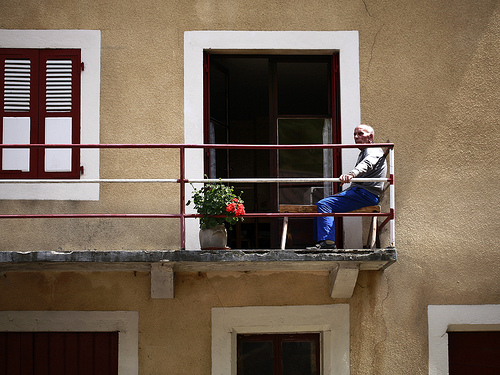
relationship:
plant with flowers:
[185, 172, 248, 230] [224, 198, 246, 217]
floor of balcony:
[2, 249, 397, 267] [5, 139, 390, 296]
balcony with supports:
[5, 139, 390, 296] [143, 270, 379, 306]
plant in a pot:
[175, 177, 247, 226] [195, 224, 230, 249]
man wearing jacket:
[306, 124, 388, 250] [344, 146, 386, 193]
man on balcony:
[306, 124, 388, 250] [1, 138, 398, 270]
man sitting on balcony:
[306, 124, 388, 250] [5, 139, 390, 296]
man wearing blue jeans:
[306, 124, 388, 250] [314, 183, 382, 242]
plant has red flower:
[185, 172, 248, 230] [222, 194, 249, 219]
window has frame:
[1, 15, 105, 198] [1, 27, 104, 202]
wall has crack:
[0, 1, 499, 374] [363, 0, 385, 77]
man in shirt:
[306, 124, 388, 250] [346, 146, 386, 189]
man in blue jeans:
[306, 124, 388, 250] [314, 183, 382, 242]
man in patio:
[306, 124, 388, 250] [11, 130, 403, 303]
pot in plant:
[197, 223, 230, 250] [175, 177, 247, 226]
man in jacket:
[306, 124, 388, 250] [349, 146, 388, 198]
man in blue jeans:
[313, 124, 387, 246] [314, 183, 376, 243]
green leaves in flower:
[185, 181, 243, 236] [225, 197, 245, 218]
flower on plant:
[226, 197, 246, 217] [151, 156, 251, 250]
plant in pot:
[185, 172, 248, 230] [186, 217, 237, 260]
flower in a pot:
[224, 192, 258, 232] [184, 172, 250, 250]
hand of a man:
[338, 174, 351, 181] [306, 124, 388, 250]